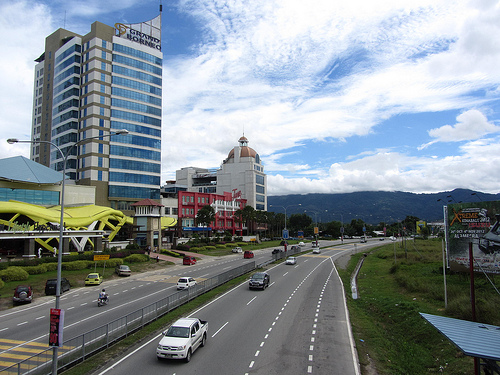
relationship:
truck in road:
[152, 317, 208, 363] [128, 264, 375, 374]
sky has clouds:
[199, 39, 394, 189] [282, 66, 345, 126]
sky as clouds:
[199, 39, 394, 189] [282, 66, 345, 126]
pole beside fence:
[47, 168, 68, 313] [121, 299, 171, 328]